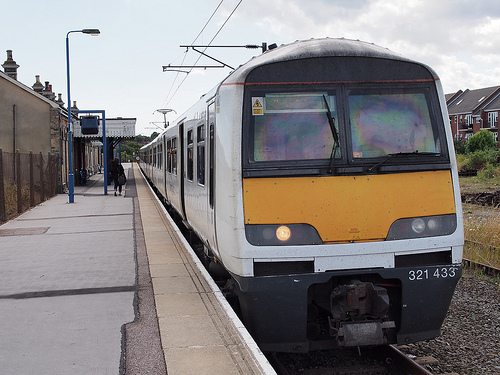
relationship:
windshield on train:
[243, 83, 452, 177] [138, 37, 468, 351]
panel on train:
[243, 168, 458, 246] [138, 37, 468, 351]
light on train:
[277, 226, 293, 241] [138, 37, 468, 351]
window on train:
[194, 124, 205, 185] [138, 37, 468, 351]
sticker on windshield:
[250, 96, 266, 120] [243, 83, 452, 177]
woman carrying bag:
[109, 157, 124, 195] [116, 172, 127, 187]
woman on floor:
[109, 157, 124, 195] [0, 162, 279, 374]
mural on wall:
[0, 177, 21, 218] [1, 71, 103, 226]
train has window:
[138, 37, 468, 351] [194, 124, 205, 185]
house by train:
[447, 85, 499, 150] [138, 37, 468, 351]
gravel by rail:
[469, 328, 477, 336] [375, 338, 432, 374]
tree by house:
[463, 129, 498, 180] [447, 85, 499, 150]